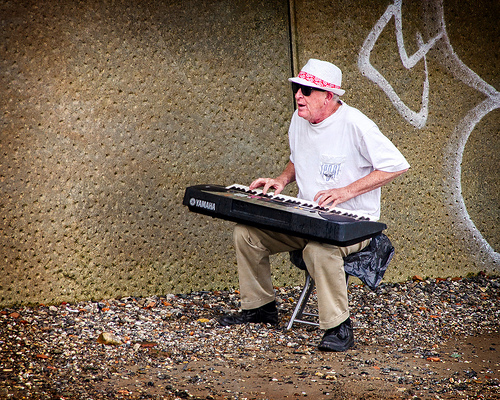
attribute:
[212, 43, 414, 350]
man — keyboard player, elderly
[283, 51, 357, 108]
hat — white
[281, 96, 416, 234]
shirt — white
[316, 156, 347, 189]
design — blue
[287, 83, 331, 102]
sunglasses — black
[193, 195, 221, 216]
lettering — white, brand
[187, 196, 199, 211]
logo — brand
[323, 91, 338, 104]
hearing aid — red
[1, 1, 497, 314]
wall — brown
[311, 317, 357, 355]
shoe — black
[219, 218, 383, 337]
pants — brown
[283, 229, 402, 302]
bag — plastic, black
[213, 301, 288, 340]
shoe — black